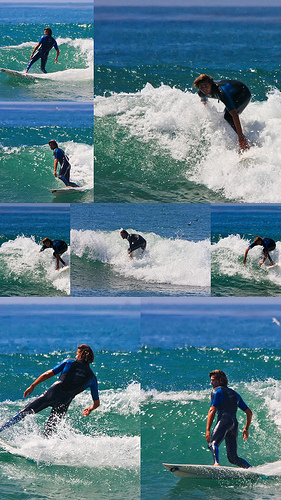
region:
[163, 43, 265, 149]
person in the water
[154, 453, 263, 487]
board in the water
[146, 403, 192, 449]
wave forming in water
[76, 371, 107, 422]
arm of the person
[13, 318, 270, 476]
two people in the photo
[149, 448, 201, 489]
front of the board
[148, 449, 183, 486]
pointy end of the board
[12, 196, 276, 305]
three photos next to each other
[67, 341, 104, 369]
hair on the man's head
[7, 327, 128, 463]
blue wetsuited guy on a surfboard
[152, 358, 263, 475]
blue wetsuited guy on a surfboard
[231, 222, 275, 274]
blue wetsuited guy on a surfboard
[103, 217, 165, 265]
blue wetsuited guy on a surfboard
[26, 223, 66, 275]
blue wetsuited guy on a surfboard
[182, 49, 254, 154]
blue wetsuited guy on a surfboard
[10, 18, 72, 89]
blue wetsuited guy standing on a surfboard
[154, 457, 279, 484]
white surfboard in the water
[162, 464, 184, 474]
ankle tag on the white surfboard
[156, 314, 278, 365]
blue ocean water in the distance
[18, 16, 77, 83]
A photo of a man on a surfboard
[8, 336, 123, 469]
A photo of a man on a surfboard leaning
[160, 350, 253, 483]
A photo of a man on a surfboard standing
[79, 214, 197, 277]
A photo of a man on a surfboard in a wave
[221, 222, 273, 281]
A photo of a man on a surfboard facing forward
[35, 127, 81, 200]
A photo of a man on a surfboard surfing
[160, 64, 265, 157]
A photo of a man on a surfboard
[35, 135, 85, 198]
A photo of a man on a surfboard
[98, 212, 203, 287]
A photo of a man on a surfboard in the waves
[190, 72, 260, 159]
A photo of a man on a surfboard reaching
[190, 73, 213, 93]
woman with blond hair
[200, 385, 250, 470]
person wearing a blue wet suit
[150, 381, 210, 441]
waves crashing into the ocean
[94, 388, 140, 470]
waves crashing into the ocean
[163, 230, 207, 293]
waves crashing into the ocean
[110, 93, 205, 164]
waves crashing into the ocean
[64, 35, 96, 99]
waves crashing into the ocean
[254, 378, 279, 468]
waves crashing into the ocean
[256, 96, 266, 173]
waves crashing into the ocean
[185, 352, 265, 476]
he is surfing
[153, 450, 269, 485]
this is a surfboard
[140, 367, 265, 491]
this is a wave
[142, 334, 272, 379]
a wave behind a wave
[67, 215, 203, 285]
this is a crashing wave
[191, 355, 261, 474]
he has on a shortsleeved wetsuit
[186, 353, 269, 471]
he is wearing a wetsuit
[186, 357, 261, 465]
his wetsuit is black and blue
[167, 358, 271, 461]
he is wet with ocean water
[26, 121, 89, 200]
he is riding on a wave